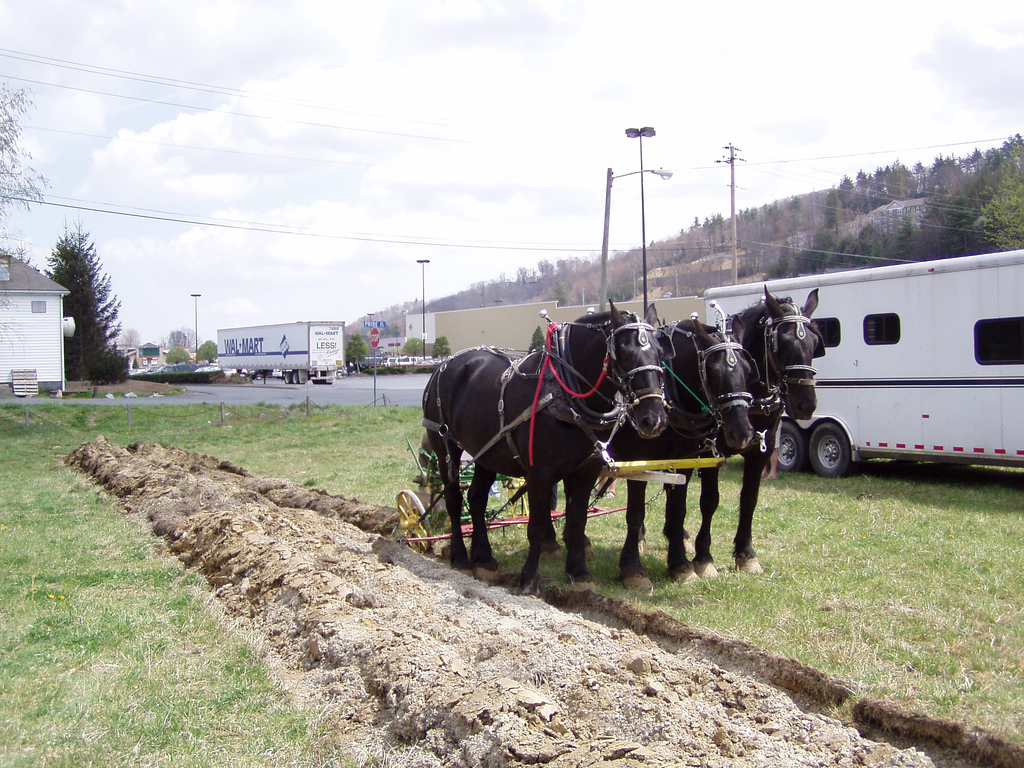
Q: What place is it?
A: It is a field.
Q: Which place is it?
A: It is a field.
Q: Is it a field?
A: Yes, it is a field.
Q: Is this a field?
A: Yes, it is a field.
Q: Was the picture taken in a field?
A: Yes, it was taken in a field.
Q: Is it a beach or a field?
A: It is a field.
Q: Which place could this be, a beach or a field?
A: It is a field.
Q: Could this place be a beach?
A: No, it is a field.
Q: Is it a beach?
A: No, it is a field.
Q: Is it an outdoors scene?
A: Yes, it is outdoors.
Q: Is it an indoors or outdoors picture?
A: It is outdoors.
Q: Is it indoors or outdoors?
A: It is outdoors.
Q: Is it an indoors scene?
A: No, it is outdoors.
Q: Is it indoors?
A: No, it is outdoors.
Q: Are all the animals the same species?
A: Yes, all the animals are horses.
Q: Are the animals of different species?
A: No, all the animals are horses.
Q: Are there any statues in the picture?
A: No, there are no statues.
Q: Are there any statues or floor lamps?
A: No, there are no statues or floor lamps.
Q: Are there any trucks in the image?
A: Yes, there is a truck.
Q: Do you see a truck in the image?
A: Yes, there is a truck.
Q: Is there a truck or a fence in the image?
A: Yes, there is a truck.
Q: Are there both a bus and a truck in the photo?
A: No, there is a truck but no buses.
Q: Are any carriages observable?
A: No, there are no carriages.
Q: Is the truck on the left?
A: Yes, the truck is on the left of the image.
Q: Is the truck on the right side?
A: No, the truck is on the left of the image.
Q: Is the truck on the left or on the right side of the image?
A: The truck is on the left of the image.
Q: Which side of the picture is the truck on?
A: The truck is on the left of the image.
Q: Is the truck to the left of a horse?
A: Yes, the truck is to the left of a horse.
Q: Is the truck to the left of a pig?
A: No, the truck is to the left of a horse.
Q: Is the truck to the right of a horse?
A: No, the truck is to the left of a horse.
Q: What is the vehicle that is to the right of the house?
A: The vehicle is a truck.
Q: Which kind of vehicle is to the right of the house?
A: The vehicle is a truck.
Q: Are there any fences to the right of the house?
A: No, there is a truck to the right of the house.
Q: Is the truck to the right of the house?
A: Yes, the truck is to the right of the house.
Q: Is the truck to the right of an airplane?
A: No, the truck is to the right of the house.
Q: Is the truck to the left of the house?
A: No, the truck is to the right of the house.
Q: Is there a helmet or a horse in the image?
A: Yes, there is a horse.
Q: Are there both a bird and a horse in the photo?
A: No, there is a horse but no birds.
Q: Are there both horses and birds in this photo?
A: No, there is a horse but no birds.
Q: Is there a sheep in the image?
A: No, there is no sheep.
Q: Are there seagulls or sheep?
A: No, there are no sheep or seagulls.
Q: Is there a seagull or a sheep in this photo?
A: No, there are no sheep or seagulls.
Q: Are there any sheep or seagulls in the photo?
A: No, there are no sheep or seagulls.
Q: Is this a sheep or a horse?
A: This is a horse.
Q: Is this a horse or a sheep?
A: This is a horse.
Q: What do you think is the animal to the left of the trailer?
A: The animal is a horse.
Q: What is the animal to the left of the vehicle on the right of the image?
A: The animal is a horse.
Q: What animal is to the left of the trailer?
A: The animal is a horse.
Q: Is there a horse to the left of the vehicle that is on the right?
A: Yes, there is a horse to the left of the trailer.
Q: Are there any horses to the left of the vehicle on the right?
A: Yes, there is a horse to the left of the trailer.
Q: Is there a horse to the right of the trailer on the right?
A: No, the horse is to the left of the trailer.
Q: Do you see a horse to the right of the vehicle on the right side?
A: No, the horse is to the left of the trailer.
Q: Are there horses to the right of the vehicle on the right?
A: No, the horse is to the left of the trailer.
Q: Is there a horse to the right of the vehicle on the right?
A: No, the horse is to the left of the trailer.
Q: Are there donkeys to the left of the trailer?
A: No, there is a horse to the left of the trailer.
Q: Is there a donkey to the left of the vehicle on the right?
A: No, there is a horse to the left of the trailer.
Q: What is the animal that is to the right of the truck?
A: The animal is a horse.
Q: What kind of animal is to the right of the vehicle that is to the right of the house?
A: The animal is a horse.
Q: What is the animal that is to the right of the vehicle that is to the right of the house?
A: The animal is a horse.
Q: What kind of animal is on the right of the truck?
A: The animal is a horse.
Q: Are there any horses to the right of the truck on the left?
A: Yes, there is a horse to the right of the truck.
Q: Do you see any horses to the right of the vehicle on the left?
A: Yes, there is a horse to the right of the truck.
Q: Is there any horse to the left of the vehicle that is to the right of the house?
A: No, the horse is to the right of the truck.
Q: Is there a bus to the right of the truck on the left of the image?
A: No, there is a horse to the right of the truck.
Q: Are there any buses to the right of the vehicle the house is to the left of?
A: No, there is a horse to the right of the truck.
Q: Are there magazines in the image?
A: No, there are no magazines.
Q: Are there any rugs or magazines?
A: No, there are no magazines or rugs.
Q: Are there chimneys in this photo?
A: No, there are no chimneys.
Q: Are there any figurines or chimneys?
A: No, there are no chimneys or figurines.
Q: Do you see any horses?
A: Yes, there is a horse.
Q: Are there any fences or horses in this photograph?
A: Yes, there is a horse.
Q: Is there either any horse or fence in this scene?
A: Yes, there is a horse.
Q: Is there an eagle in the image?
A: No, there are no eagles.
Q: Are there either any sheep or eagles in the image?
A: No, there are no eagles or sheep.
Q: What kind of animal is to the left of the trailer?
A: The animal is a horse.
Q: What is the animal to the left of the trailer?
A: The animal is a horse.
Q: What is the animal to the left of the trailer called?
A: The animal is a horse.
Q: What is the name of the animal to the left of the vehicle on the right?
A: The animal is a horse.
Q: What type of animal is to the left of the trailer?
A: The animal is a horse.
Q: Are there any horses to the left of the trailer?
A: Yes, there is a horse to the left of the trailer.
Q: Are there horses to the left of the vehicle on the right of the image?
A: Yes, there is a horse to the left of the trailer.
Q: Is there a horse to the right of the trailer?
A: No, the horse is to the left of the trailer.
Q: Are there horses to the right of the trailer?
A: No, the horse is to the left of the trailer.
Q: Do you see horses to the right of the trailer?
A: No, the horse is to the left of the trailer.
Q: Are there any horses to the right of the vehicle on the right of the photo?
A: No, the horse is to the left of the trailer.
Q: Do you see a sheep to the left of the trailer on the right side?
A: No, there is a horse to the left of the trailer.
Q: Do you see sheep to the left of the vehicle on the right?
A: No, there is a horse to the left of the trailer.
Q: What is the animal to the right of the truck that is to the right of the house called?
A: The animal is a horse.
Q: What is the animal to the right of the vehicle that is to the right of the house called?
A: The animal is a horse.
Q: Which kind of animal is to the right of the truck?
A: The animal is a horse.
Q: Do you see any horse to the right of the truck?
A: Yes, there is a horse to the right of the truck.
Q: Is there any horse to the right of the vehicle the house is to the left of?
A: Yes, there is a horse to the right of the truck.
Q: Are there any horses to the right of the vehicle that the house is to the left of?
A: Yes, there is a horse to the right of the truck.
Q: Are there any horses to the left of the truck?
A: No, the horse is to the right of the truck.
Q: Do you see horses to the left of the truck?
A: No, the horse is to the right of the truck.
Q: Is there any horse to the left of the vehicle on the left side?
A: No, the horse is to the right of the truck.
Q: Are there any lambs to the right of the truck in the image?
A: No, there is a horse to the right of the truck.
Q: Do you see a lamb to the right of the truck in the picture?
A: No, there is a horse to the right of the truck.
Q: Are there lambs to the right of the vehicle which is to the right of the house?
A: No, there is a horse to the right of the truck.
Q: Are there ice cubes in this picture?
A: No, there are no ice cubes.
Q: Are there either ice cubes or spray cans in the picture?
A: No, there are no ice cubes or spray cans.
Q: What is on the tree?
A: The leaves are on the tree.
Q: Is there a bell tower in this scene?
A: No, there are no bell towers.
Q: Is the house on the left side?
A: Yes, the house is on the left of the image.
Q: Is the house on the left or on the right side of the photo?
A: The house is on the left of the image.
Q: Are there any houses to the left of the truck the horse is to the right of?
A: Yes, there is a house to the left of the truck.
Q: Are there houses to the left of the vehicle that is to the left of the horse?
A: Yes, there is a house to the left of the truck.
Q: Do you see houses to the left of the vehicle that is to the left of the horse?
A: Yes, there is a house to the left of the truck.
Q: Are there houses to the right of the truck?
A: No, the house is to the left of the truck.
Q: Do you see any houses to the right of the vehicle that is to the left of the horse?
A: No, the house is to the left of the truck.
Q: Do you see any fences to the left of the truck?
A: No, there is a house to the left of the truck.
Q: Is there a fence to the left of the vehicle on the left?
A: No, there is a house to the left of the truck.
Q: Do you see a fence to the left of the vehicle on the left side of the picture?
A: No, there is a house to the left of the truck.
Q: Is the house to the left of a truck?
A: Yes, the house is to the left of a truck.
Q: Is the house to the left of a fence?
A: No, the house is to the left of a truck.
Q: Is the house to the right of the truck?
A: No, the house is to the left of the truck.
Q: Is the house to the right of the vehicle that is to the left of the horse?
A: No, the house is to the left of the truck.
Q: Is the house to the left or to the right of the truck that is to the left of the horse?
A: The house is to the left of the truck.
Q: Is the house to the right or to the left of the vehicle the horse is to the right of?
A: The house is to the left of the truck.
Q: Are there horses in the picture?
A: Yes, there is a horse.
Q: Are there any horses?
A: Yes, there is a horse.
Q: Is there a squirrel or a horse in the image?
A: Yes, there is a horse.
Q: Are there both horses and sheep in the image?
A: No, there is a horse but no sheep.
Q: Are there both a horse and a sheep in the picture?
A: No, there is a horse but no sheep.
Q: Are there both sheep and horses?
A: No, there is a horse but no sheep.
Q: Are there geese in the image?
A: No, there are no geese.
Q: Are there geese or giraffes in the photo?
A: No, there are no geese or giraffes.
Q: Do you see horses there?
A: Yes, there is a horse.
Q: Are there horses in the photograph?
A: Yes, there is a horse.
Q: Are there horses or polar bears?
A: Yes, there is a horse.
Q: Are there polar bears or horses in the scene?
A: Yes, there is a horse.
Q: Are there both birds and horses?
A: No, there is a horse but no birds.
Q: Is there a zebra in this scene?
A: No, there are no zebras.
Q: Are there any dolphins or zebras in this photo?
A: No, there are no zebras or dolphins.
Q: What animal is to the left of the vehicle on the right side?
A: The animal is a horse.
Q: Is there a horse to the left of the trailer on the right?
A: Yes, there is a horse to the left of the trailer.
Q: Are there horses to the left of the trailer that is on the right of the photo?
A: Yes, there is a horse to the left of the trailer.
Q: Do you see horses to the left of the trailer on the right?
A: Yes, there is a horse to the left of the trailer.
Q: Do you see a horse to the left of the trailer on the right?
A: Yes, there is a horse to the left of the trailer.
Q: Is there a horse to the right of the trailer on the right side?
A: No, the horse is to the left of the trailer.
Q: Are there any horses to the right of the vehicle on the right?
A: No, the horse is to the left of the trailer.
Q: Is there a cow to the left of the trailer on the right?
A: No, there is a horse to the left of the trailer.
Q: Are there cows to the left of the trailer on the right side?
A: No, there is a horse to the left of the trailer.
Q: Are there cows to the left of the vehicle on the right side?
A: No, there is a horse to the left of the trailer.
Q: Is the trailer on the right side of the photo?
A: Yes, the trailer is on the right of the image.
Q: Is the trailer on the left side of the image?
A: No, the trailer is on the right of the image.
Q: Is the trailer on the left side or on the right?
A: The trailer is on the right of the image.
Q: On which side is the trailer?
A: The trailer is on the right of the image.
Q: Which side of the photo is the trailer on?
A: The trailer is on the right of the image.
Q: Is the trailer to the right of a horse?
A: Yes, the trailer is to the right of a horse.